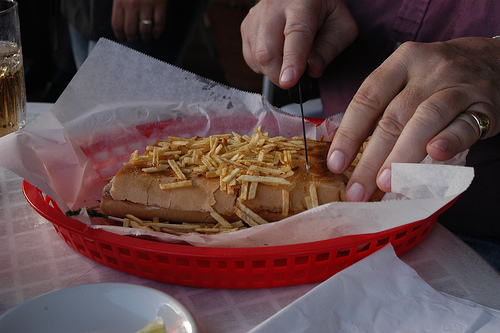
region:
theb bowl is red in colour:
[208, 250, 298, 296]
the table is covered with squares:
[3, 226, 38, 271]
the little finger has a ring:
[445, 103, 497, 152]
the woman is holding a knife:
[249, 39, 324, 188]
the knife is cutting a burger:
[209, 8, 394, 220]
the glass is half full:
[0, 2, 24, 136]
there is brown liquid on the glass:
[1, 4, 26, 139]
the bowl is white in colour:
[18, 294, 184, 329]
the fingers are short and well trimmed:
[327, 145, 402, 202]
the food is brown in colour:
[125, 135, 305, 212]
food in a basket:
[34, 65, 464, 269]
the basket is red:
[30, 166, 489, 308]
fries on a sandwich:
[86, 129, 342, 216]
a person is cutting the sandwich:
[262, 53, 341, 183]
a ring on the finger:
[448, 101, 498, 164]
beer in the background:
[3, 4, 40, 134]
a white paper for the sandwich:
[45, 40, 229, 135]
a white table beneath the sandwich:
[14, 233, 471, 328]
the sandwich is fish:
[99, 189, 277, 230]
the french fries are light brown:
[147, 132, 285, 180]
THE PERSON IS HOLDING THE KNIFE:
[278, 43, 337, 193]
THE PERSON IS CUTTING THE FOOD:
[274, 55, 324, 230]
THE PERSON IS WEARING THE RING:
[461, 100, 498, 165]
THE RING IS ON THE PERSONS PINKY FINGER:
[456, 104, 496, 153]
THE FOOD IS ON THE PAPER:
[86, 114, 400, 246]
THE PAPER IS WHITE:
[0, 30, 492, 250]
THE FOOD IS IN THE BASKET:
[91, 121, 398, 247]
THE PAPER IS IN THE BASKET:
[0, 33, 495, 302]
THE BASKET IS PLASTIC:
[10, 113, 453, 311]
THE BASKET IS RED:
[23, 104, 448, 298]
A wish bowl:
[1, 285, 203, 332]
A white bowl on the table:
[2, 283, 192, 332]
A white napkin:
[294, 290, 495, 332]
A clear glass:
[1, 4, 33, 139]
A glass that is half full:
[2, 4, 38, 143]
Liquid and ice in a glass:
[0, 36, 31, 141]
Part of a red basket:
[200, 248, 313, 284]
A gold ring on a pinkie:
[468, 103, 498, 137]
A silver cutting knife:
[293, 77, 320, 174]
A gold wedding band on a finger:
[138, 12, 153, 27]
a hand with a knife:
[247, 1, 356, 181]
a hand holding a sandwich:
[329, 39, 499, 201]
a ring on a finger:
[460, 97, 493, 154]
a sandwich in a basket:
[69, 111, 417, 263]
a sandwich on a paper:
[86, 124, 387, 244]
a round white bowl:
[9, 277, 230, 327]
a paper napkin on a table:
[267, 249, 489, 322]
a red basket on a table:
[69, 190, 434, 284]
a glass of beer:
[4, 8, 63, 142]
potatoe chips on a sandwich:
[165, 121, 344, 199]